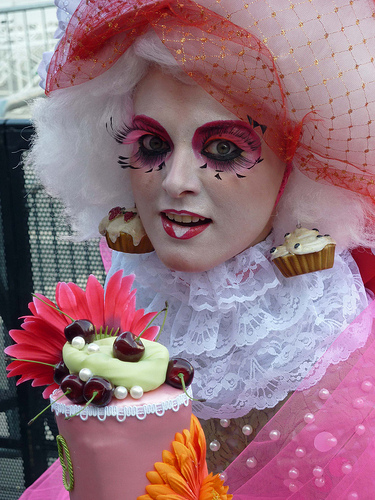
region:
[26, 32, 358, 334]
Woman in make-up and costume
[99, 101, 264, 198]
Woman with feathers on eyelashes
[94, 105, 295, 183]
Woman with heavy eye make-up and super long lashes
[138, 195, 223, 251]
Pink and white lipstick on lips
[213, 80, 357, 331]
Fake cupcake on a women's dress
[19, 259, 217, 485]
Cherries and flowers on a costume piece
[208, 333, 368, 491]
White beads on pink chiffon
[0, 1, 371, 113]
Red and gold net on white wig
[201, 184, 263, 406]
White lace collar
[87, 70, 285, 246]
Wild eyes with heavy costume make-up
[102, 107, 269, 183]
the lady has long eyelashes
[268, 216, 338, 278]
the earring is a cupcake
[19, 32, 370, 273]
the lady's hair is white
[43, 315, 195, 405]
the cherries are dark red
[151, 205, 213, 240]
the lady has pink lips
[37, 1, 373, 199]
the hair net is red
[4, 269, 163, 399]
the flower is pink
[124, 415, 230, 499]
the flower is orange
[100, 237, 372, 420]
the lady has lace around her neck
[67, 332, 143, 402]
pearls near the cherries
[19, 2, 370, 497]
a woman wearing a costume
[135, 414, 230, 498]
orange petals of a flower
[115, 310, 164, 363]
a red cherry with a green stem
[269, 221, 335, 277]
a cupcake with white frosting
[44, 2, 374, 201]
a red veil on woman's head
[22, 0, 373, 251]
a white wig on woman's head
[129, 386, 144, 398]
a white pearl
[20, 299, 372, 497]
a pink veil around woman's shoulder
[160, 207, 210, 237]
woman with pink and white lipstick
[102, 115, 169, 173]
woman with long eyelashes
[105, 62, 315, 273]
woman wearing makeup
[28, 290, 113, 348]
the cherry beside the flower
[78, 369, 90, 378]
the pearl above the cherries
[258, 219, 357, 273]
the cupcake earring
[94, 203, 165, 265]
the cupcake earring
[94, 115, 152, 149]
the eyelashes are long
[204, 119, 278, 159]
the eyelashes are long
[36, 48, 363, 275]
the woman has white hair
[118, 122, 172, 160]
the eye of the woman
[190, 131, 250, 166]
the eye of the woman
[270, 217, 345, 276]
cupcake on the woman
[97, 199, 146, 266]
strawberry cupcake on woman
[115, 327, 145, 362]
cherry on top of dish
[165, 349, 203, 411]
a cherry on surface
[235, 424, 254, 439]
white pearl on the woman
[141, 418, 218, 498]
orange flower on the model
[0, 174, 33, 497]
black fence in the background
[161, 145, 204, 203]
the nose on the woman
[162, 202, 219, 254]
the woman's pink lips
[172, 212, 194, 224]
the woman's front teeth